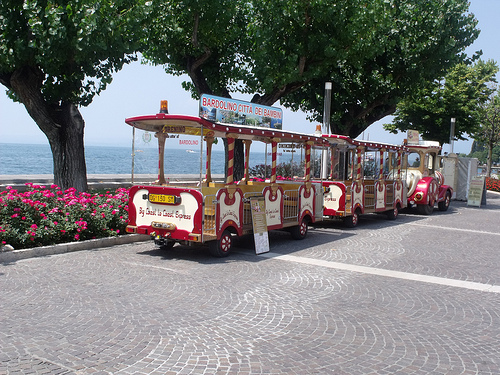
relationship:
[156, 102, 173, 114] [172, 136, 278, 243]
light on train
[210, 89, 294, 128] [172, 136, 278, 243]
sign on train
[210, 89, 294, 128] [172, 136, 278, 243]
sign next to train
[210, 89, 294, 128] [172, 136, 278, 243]
sign near train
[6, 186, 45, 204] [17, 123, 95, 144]
flowers under tree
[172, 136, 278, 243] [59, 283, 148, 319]
train on ground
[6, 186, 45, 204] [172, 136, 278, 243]
flowers next to train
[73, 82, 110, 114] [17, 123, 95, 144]
branch of tree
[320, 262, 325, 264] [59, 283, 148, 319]
line on ground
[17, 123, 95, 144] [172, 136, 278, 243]
tree next to train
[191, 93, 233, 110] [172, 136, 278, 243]
words on train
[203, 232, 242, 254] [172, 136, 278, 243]
tire of train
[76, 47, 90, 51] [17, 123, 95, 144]
leaves on tree